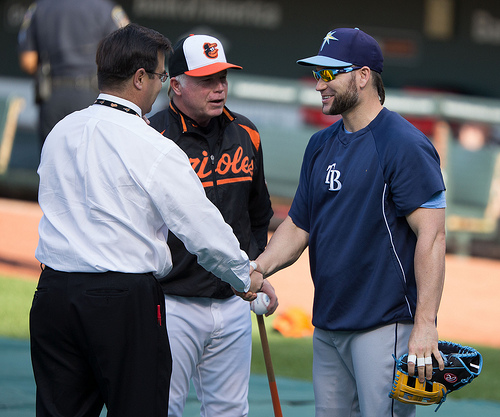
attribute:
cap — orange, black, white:
[172, 29, 244, 77]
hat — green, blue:
[294, 25, 394, 75]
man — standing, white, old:
[27, 11, 180, 416]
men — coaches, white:
[169, 19, 442, 416]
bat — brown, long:
[248, 310, 300, 412]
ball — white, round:
[247, 288, 283, 320]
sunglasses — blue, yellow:
[301, 66, 352, 79]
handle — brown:
[244, 294, 273, 345]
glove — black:
[395, 332, 476, 411]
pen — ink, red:
[145, 300, 167, 329]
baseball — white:
[245, 291, 270, 318]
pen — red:
[150, 298, 164, 330]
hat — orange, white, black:
[155, 37, 236, 86]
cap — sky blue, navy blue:
[302, 27, 378, 83]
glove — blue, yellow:
[386, 340, 478, 397]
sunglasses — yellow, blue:
[307, 69, 347, 84]